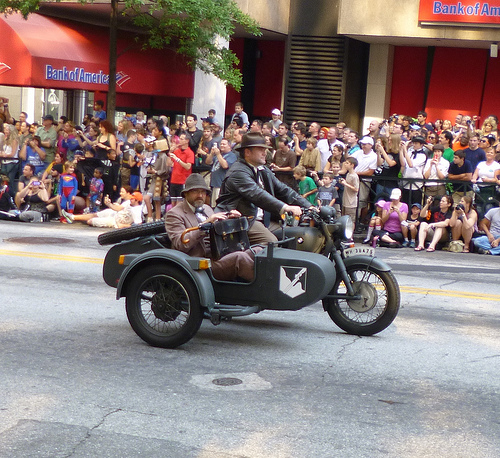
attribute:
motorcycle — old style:
[90, 196, 407, 358]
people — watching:
[3, 98, 216, 186]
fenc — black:
[360, 170, 451, 199]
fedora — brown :
[233, 128, 281, 151]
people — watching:
[292, 109, 499, 224]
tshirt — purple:
[377, 201, 410, 230]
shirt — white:
[421, 155, 454, 189]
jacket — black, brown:
[211, 160, 314, 228]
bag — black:
[206, 219, 249, 256]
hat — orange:
[390, 46, 499, 115]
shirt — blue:
[446, 150, 483, 193]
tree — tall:
[6, 2, 257, 112]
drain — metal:
[206, 370, 246, 394]